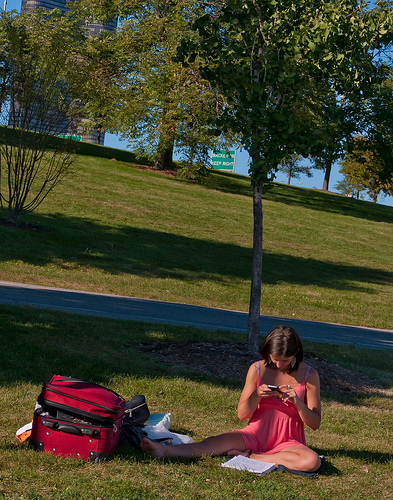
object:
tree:
[200, 0, 383, 355]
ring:
[288, 385, 291, 388]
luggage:
[30, 374, 151, 457]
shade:
[2, 305, 391, 404]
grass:
[36, 302, 356, 414]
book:
[221, 454, 277, 476]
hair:
[262, 326, 304, 375]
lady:
[140, 326, 322, 473]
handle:
[54, 424, 83, 436]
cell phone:
[268, 385, 279, 390]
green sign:
[211, 148, 236, 172]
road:
[126, 129, 295, 161]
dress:
[228, 363, 312, 455]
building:
[8, 0, 120, 147]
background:
[2, 2, 392, 208]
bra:
[255, 361, 309, 405]